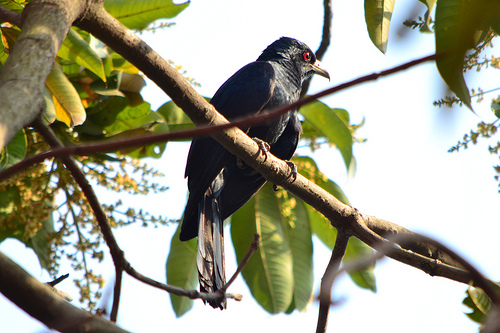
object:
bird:
[178, 36, 331, 313]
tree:
[1, 0, 498, 333]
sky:
[1, 0, 498, 333]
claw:
[272, 159, 298, 191]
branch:
[85, 0, 499, 333]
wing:
[183, 60, 277, 221]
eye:
[303, 51, 312, 62]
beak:
[312, 59, 330, 82]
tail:
[194, 181, 227, 311]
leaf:
[231, 177, 297, 317]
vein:
[249, 188, 277, 315]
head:
[258, 36, 331, 83]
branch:
[176, 36, 331, 310]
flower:
[491, 54, 499, 71]